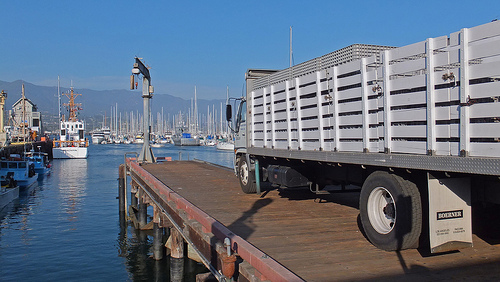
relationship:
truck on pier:
[187, 18, 500, 245] [113, 141, 499, 282]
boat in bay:
[44, 73, 96, 161] [0, 133, 271, 281]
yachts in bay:
[85, 85, 268, 152] [0, 133, 271, 281]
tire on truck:
[338, 159, 440, 253] [187, 18, 500, 245]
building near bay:
[5, 78, 48, 162] [0, 133, 271, 281]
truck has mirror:
[187, 18, 500, 245] [220, 101, 237, 127]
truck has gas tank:
[187, 18, 500, 245] [258, 155, 326, 195]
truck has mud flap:
[187, 18, 500, 245] [419, 163, 480, 262]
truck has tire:
[187, 18, 500, 245] [338, 159, 440, 253]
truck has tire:
[187, 18, 500, 245] [229, 150, 262, 202]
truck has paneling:
[187, 18, 500, 245] [248, 21, 500, 158]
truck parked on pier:
[187, 18, 500, 245] [113, 141, 499, 282]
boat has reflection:
[44, 73, 96, 161] [48, 157, 91, 227]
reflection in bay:
[48, 157, 91, 227] [0, 133, 271, 281]